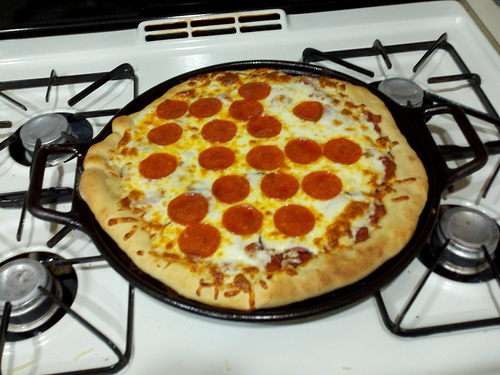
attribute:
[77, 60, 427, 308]
pizza — delicious, baked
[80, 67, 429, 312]
crust —  brown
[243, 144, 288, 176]
pepperoni — red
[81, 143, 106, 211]
puffy — on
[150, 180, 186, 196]
cheese — white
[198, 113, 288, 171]
toppings — on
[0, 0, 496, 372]
stove top —  gas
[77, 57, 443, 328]
pizza — homemade, cooked through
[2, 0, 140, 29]
back —  of the stove,  black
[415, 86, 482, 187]
handle — on